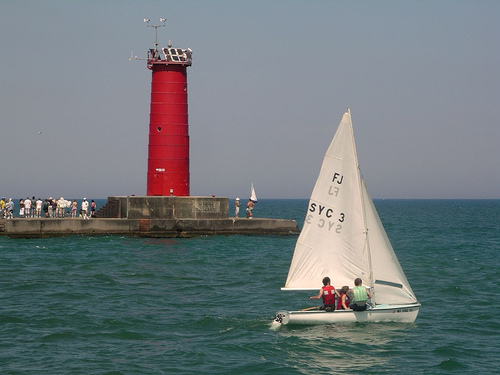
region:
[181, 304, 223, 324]
ripple of wave in ocean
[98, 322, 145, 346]
ripple of wave in ocean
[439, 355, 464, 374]
ripple of wave in ocean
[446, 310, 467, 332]
ripple of wave in ocean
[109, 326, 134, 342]
ripple of wave in ocean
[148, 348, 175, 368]
ripple of wave in ocean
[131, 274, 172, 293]
ripple of wave in ocean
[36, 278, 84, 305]
ripple of wave in ocean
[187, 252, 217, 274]
ripple of wave in ocean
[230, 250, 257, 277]
ripple of wave in ocean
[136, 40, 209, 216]
a red light house.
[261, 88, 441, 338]
a white sailboat.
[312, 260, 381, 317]
people on a boat.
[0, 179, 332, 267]
a lighthouse area.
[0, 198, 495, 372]
a large body of water.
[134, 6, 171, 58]
a tall light.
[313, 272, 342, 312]
a woman on a boat.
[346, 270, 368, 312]
a person on a sail boat.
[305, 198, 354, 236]
writing on a sail.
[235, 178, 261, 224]
a small sail boat.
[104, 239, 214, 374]
the sea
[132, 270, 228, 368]
the sea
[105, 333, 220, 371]
the sea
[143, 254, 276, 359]
the sea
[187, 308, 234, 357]
the sea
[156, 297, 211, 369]
the sea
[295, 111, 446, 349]
white boat on water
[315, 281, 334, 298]
person has dark hair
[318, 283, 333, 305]
person wears red life jacket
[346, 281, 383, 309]
person wears green life jacket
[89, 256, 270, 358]
water is blue and wavy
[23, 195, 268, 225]
grey pier with people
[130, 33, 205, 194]
red lighthouse on pier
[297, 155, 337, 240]
black letters on white sail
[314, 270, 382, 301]
three people on boat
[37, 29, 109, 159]
sky is blue and hazy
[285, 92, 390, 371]
the sailboat is white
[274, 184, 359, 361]
the sailboat is white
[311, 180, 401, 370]
the sailboat is white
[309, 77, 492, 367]
the sailboat is white